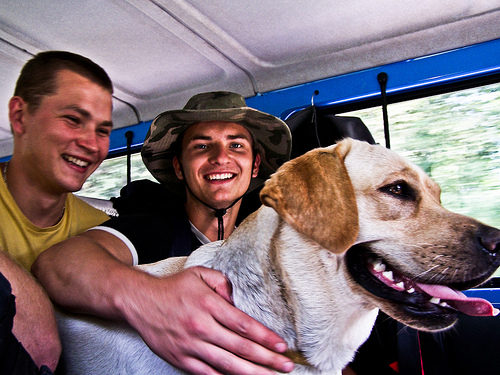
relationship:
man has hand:
[35, 100, 340, 374] [156, 263, 296, 374]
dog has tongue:
[50, 139, 500, 362] [421, 280, 498, 327]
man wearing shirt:
[1, 49, 126, 322] [1, 166, 110, 261]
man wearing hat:
[35, 100, 340, 374] [145, 90, 289, 184]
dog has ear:
[50, 139, 500, 362] [261, 144, 368, 254]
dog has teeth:
[50, 139, 500, 362] [373, 260, 433, 292]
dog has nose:
[50, 139, 500, 362] [478, 225, 499, 249]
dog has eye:
[50, 139, 500, 362] [380, 183, 416, 200]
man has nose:
[35, 100, 340, 374] [213, 144, 228, 169]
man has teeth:
[35, 100, 340, 374] [207, 173, 237, 177]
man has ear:
[35, 100, 340, 374] [170, 156, 189, 180]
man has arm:
[35, 100, 340, 374] [36, 214, 294, 370]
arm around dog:
[36, 214, 294, 370] [50, 139, 500, 362]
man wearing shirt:
[35, 100, 340, 374] [102, 178, 268, 263]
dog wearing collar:
[50, 139, 500, 362] [286, 344, 332, 373]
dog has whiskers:
[50, 139, 500, 362] [391, 237, 465, 286]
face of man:
[182, 121, 252, 204] [35, 100, 340, 374]